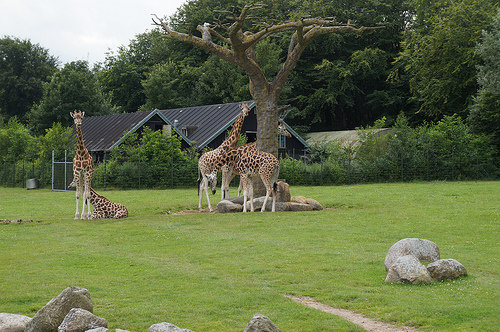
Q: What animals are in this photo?
A: Giraffes.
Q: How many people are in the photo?
A: None.